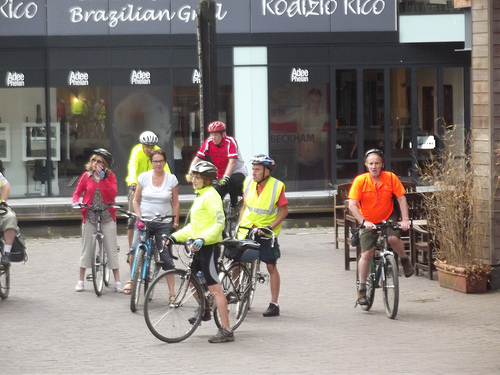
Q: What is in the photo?
A: Bikes.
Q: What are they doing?
A: Riding.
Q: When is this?
A: Daytime.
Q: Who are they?
A: Cyclists.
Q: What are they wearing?
A: Protective pads.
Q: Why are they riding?
A: Fun.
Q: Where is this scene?
A: Outside on the sidewalk.